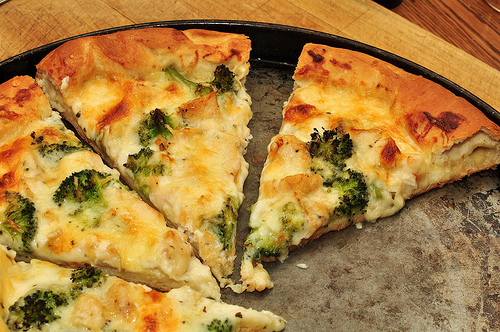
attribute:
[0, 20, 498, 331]
tray — grey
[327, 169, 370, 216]
broccoli — green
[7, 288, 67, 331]
broccoli — green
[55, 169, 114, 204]
broccoli — green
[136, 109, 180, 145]
broccoli — green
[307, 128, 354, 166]
broccoli — green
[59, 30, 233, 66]
crust — brown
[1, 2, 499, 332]
table — brown, wood, wooden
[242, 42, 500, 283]
slice — triangle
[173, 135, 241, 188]
cheese — white